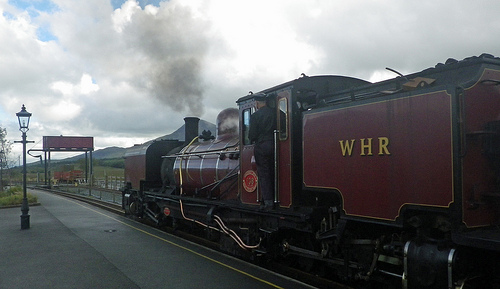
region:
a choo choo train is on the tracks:
[122, 60, 493, 285]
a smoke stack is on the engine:
[181, 113, 203, 146]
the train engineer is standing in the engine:
[242, 87, 292, 216]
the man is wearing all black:
[247, 108, 287, 203]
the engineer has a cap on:
[251, 90, 272, 112]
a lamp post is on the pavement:
[8, 103, 40, 240]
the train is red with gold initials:
[124, 72, 494, 279]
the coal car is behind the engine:
[301, 50, 497, 275]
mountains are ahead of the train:
[13, 95, 285, 255]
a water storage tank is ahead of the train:
[26, 132, 110, 202]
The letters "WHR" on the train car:
[335, 135, 395, 158]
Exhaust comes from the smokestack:
[130, 3, 208, 115]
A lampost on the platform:
[12, 101, 39, 231]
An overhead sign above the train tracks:
[38, 131, 108, 155]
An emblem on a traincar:
[239, 167, 259, 194]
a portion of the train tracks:
[26, 180, 118, 211]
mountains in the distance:
[6, 144, 143, 162]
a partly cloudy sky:
[5, 3, 85, 133]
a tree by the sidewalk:
[2, 126, 14, 191]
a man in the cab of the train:
[245, 92, 283, 209]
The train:
[225, 61, 411, 216]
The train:
[217, 106, 337, 254]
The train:
[211, 89, 293, 214]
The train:
[239, 114, 277, 176]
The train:
[269, 137, 341, 241]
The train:
[302, 104, 399, 285]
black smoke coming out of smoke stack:
[95, 17, 220, 99]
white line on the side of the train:
[175, 170, 255, 237]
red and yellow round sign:
[229, 165, 268, 194]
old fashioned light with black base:
[7, 100, 50, 245]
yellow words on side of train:
[312, 125, 406, 168]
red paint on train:
[289, 99, 460, 218]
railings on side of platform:
[70, 164, 126, 212]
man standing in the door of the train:
[246, 94, 285, 200]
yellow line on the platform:
[140, 218, 270, 270]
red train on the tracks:
[76, 61, 434, 233]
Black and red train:
[112, 120, 498, 269]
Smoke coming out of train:
[136, 12, 222, 150]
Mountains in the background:
[75, 112, 150, 167]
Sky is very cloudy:
[10, 8, 127, 110]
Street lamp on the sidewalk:
[11, 107, 43, 239]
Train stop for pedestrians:
[40, 132, 97, 194]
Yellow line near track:
[48, 182, 220, 285]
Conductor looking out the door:
[238, 85, 283, 210]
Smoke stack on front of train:
[169, 104, 216, 179]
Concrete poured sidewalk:
[45, 194, 152, 269]